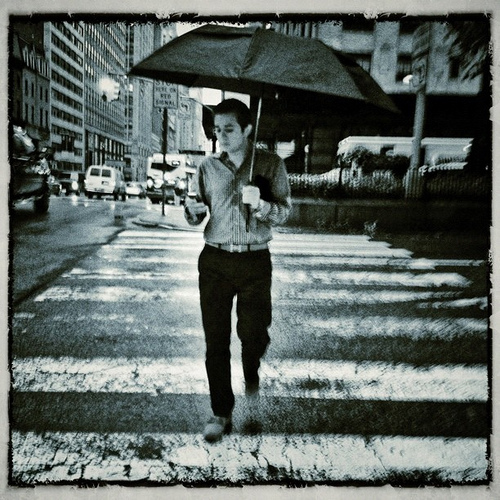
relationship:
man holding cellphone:
[183, 99, 292, 440] [174, 184, 205, 229]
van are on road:
[80, 165, 127, 202] [12, 188, 498, 498]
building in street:
[11, 19, 197, 201] [10, 185, 488, 493]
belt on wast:
[201, 240, 273, 254] [198, 219, 275, 266]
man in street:
[183, 99, 292, 440] [271, 247, 354, 380]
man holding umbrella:
[183, 99, 292, 440] [179, 27, 374, 124]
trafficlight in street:
[94, 75, 127, 101] [34, 169, 499, 489]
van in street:
[80, 165, 127, 202] [10, 185, 488, 493]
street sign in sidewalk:
[155, 102, 174, 224] [139, 174, 498, 236]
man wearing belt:
[183, 99, 292, 440] [185, 225, 305, 277]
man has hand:
[183, 99, 292, 440] [181, 193, 211, 227]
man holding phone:
[183, 99, 292, 440] [183, 189, 207, 226]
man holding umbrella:
[183, 99, 292, 440] [128, 22, 400, 234]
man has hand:
[183, 99, 292, 440] [241, 177, 261, 208]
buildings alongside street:
[87, 24, 132, 184] [10, 185, 488, 493]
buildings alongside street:
[43, 19, 83, 180] [10, 185, 488, 493]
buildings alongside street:
[130, 20, 152, 180] [10, 185, 488, 493]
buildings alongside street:
[150, 22, 175, 183] [10, 185, 488, 493]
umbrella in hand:
[123, 23, 399, 120] [238, 183, 260, 210]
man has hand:
[183, 99, 292, 440] [238, 183, 260, 210]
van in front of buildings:
[80, 165, 127, 202] [87, 24, 132, 184]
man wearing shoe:
[183, 99, 292, 440] [194, 404, 241, 446]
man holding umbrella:
[165, 90, 297, 440] [95, 25, 449, 114]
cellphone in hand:
[187, 192, 206, 218] [185, 198, 208, 216]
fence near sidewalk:
[288, 165, 493, 200] [133, 202, 488, 234]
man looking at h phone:
[183, 99, 292, 440] [185, 192, 202, 204]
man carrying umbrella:
[165, 90, 297, 440] [119, 15, 397, 221]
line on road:
[11, 354, 487, 404] [12, 188, 498, 498]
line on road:
[9, 434, 489, 481] [12, 188, 498, 498]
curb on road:
[134, 215, 169, 233] [12, 188, 498, 498]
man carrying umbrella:
[183, 99, 292, 440] [113, 9, 433, 154]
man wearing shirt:
[183, 99, 292, 440] [180, 149, 292, 246]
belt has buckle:
[201, 234, 273, 255] [224, 240, 246, 254]